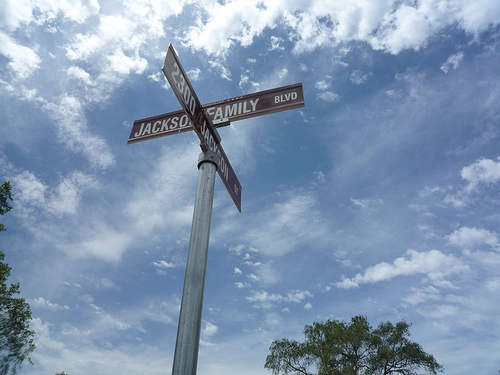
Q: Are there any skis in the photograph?
A: No, there are no skis.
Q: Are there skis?
A: No, there are no skis.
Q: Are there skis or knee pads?
A: No, there are no skis or knee pads.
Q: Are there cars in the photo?
A: No, there are no cars.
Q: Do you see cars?
A: No, there are no cars.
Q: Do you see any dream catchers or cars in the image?
A: No, there are no cars or dream catchers.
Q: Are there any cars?
A: No, there are no cars.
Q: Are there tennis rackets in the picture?
A: No, there are no tennis rackets.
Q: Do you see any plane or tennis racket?
A: No, there are no rackets or airplanes.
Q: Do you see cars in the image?
A: No, there are no cars.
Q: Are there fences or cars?
A: No, there are no cars or fences.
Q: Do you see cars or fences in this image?
A: No, there are no cars or fences.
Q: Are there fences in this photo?
A: No, there are no fences.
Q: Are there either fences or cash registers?
A: No, there are no fences or cash registers.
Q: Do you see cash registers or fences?
A: No, there are no fences or cash registers.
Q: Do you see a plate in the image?
A: Yes, there is a plate.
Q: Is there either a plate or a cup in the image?
A: Yes, there is a plate.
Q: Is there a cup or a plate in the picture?
A: Yes, there is a plate.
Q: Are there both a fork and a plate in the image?
A: No, there is a plate but no forks.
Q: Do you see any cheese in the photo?
A: No, there is no cheese.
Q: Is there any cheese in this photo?
A: No, there is no cheese.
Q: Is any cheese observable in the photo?
A: No, there is no cheese.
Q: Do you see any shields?
A: No, there are no shields.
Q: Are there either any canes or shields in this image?
A: No, there are no shields or canes.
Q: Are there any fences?
A: No, there are no fences.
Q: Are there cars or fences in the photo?
A: No, there are no fences or cars.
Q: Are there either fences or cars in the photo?
A: No, there are no fences or cars.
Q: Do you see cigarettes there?
A: No, there are no cigarettes.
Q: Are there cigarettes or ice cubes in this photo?
A: No, there are no cigarettes or ice cubes.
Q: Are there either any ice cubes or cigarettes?
A: No, there are no cigarettes or ice cubes.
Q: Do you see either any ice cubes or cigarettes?
A: No, there are no cigarettes or ice cubes.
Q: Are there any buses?
A: No, there are no buses.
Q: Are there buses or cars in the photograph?
A: No, there are no buses or cars.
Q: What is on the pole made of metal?
A: The sign is on the pole.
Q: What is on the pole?
A: The sign is on the pole.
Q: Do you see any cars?
A: No, there are no cars.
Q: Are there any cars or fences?
A: No, there are no cars or fences.